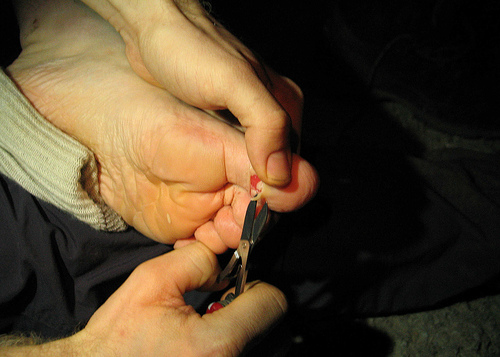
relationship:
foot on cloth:
[1, 0, 318, 255] [0, 67, 126, 232]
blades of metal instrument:
[241, 197, 253, 238] [197, 199, 270, 316]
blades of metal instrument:
[252, 205, 274, 238] [197, 199, 270, 316]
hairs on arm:
[1, 321, 94, 355] [1, 320, 152, 353]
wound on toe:
[247, 178, 265, 191] [226, 127, 315, 214]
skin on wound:
[248, 171, 263, 200] [245, 163, 312, 220]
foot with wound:
[8, 42, 318, 247] [247, 178, 265, 191]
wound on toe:
[247, 178, 265, 191] [216, 136, 316, 215]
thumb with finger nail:
[228, 76, 293, 186] [265, 150, 287, 182]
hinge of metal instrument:
[237, 239, 249, 257] [197, 199, 270, 316]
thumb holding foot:
[234, 76, 295, 188] [8, 42, 318, 247]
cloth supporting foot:
[0, 57, 130, 234] [1, 0, 318, 255]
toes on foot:
[165, 210, 256, 252] [1, 10, 332, 317]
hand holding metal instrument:
[73, 238, 287, 357] [197, 199, 270, 316]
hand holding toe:
[88, 0, 308, 194] [230, 145, 320, 222]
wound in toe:
[235, 173, 277, 208] [225, 129, 325, 209]